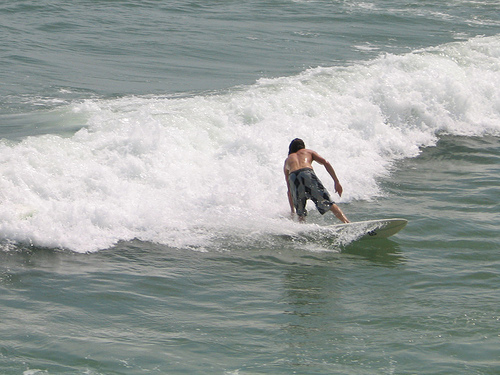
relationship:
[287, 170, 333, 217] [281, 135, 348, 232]
shorts on man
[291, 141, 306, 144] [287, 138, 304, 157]
hair on head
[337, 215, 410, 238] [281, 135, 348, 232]
surfboard under man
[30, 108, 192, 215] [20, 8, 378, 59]
wave in water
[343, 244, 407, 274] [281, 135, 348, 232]
shadow of man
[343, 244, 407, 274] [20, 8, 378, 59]
shadow in water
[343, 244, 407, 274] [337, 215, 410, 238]
shadow of surfboard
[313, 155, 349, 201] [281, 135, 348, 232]
arm of man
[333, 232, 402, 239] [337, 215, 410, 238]
bottom of surfboard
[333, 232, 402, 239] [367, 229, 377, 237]
bottom has logo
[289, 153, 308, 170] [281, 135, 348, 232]
back of man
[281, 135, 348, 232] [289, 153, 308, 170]
man has back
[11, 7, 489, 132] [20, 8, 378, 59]
ocean has water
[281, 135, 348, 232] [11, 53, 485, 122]
person on waves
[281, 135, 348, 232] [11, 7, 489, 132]
person on ocean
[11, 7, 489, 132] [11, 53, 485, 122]
ocean has waves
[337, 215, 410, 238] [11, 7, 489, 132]
surfboard in ocean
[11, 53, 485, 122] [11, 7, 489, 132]
waves in ocean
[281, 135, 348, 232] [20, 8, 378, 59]
man in water